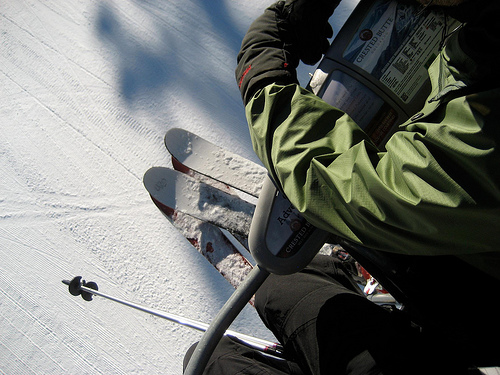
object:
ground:
[45, 93, 119, 253]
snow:
[45, 107, 124, 234]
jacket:
[227, 28, 471, 278]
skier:
[220, 48, 427, 268]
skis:
[123, 105, 249, 277]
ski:
[33, 246, 183, 364]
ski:
[135, 102, 283, 319]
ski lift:
[156, 193, 260, 303]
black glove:
[217, 8, 318, 90]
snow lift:
[334, 22, 444, 145]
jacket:
[201, 34, 444, 240]